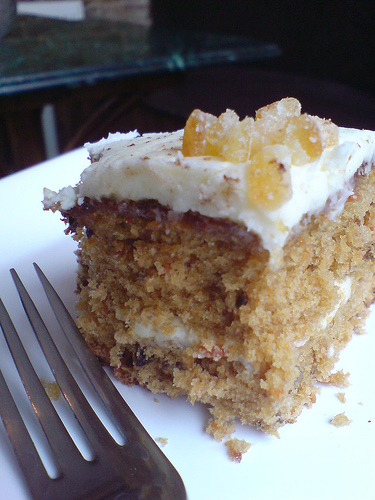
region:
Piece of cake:
[72, 118, 373, 424]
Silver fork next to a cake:
[1, 259, 185, 495]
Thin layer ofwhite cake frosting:
[52, 117, 373, 240]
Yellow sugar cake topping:
[175, 92, 333, 205]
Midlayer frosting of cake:
[69, 278, 373, 358]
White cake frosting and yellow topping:
[66, 101, 372, 248]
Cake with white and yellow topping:
[59, 84, 374, 441]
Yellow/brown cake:
[64, 196, 373, 426]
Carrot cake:
[65, 111, 373, 431]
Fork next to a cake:
[0, 260, 237, 497]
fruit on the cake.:
[190, 88, 334, 194]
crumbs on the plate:
[204, 359, 357, 459]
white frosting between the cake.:
[283, 274, 353, 347]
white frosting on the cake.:
[48, 115, 372, 228]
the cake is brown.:
[69, 183, 371, 406]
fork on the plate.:
[2, 259, 192, 497]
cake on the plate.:
[56, 94, 374, 432]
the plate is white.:
[0, 121, 373, 498]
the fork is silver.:
[0, 263, 192, 496]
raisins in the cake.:
[128, 340, 153, 364]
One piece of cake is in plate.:
[52, 135, 348, 408]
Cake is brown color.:
[141, 236, 299, 374]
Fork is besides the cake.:
[28, 366, 137, 476]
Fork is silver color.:
[40, 379, 154, 479]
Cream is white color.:
[102, 140, 216, 204]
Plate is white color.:
[180, 425, 340, 490]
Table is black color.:
[12, 26, 176, 80]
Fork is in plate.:
[75, 432, 226, 498]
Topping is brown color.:
[191, 105, 296, 157]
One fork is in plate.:
[9, 116, 258, 252]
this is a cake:
[87, 148, 357, 371]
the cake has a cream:
[134, 119, 335, 202]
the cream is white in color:
[136, 162, 223, 197]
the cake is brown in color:
[130, 258, 275, 323]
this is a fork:
[7, 365, 101, 441]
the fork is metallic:
[0, 344, 96, 426]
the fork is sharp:
[12, 271, 59, 327]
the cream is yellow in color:
[182, 104, 307, 160]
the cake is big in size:
[132, 186, 366, 412]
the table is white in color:
[254, 444, 310, 489]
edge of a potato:
[194, 122, 219, 140]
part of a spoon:
[116, 459, 143, 492]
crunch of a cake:
[226, 454, 242, 471]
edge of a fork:
[143, 432, 174, 471]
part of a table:
[188, 447, 219, 479]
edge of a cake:
[188, 319, 249, 420]